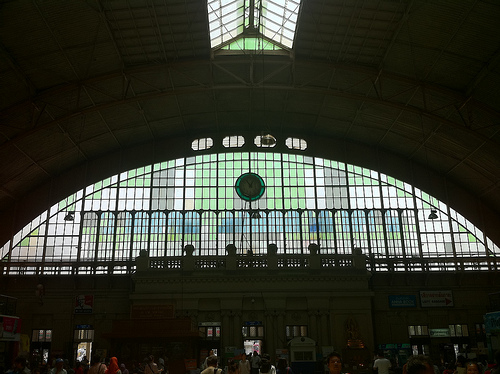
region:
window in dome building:
[19, 315, 59, 347]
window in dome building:
[64, 319, 103, 343]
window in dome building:
[233, 315, 271, 341]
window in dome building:
[272, 318, 314, 339]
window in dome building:
[400, 316, 430, 340]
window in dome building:
[441, 312, 470, 349]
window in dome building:
[176, 131, 223, 157]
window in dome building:
[213, 126, 249, 157]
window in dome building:
[246, 124, 278, 153]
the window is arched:
[17, 150, 432, 225]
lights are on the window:
[115, 219, 492, 362]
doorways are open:
[21, 320, 123, 367]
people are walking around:
[182, 338, 256, 373]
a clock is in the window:
[208, 165, 372, 215]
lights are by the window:
[52, 192, 146, 268]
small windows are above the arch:
[176, 125, 458, 215]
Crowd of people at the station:
[6, 342, 484, 370]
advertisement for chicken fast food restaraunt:
[75, 292, 92, 309]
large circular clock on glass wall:
[235, 170, 265, 202]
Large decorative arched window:
[2, 153, 499, 258]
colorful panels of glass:
[169, 211, 203, 238]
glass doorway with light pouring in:
[239, 331, 266, 363]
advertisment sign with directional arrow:
[417, 289, 456, 309]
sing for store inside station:
[0, 317, 20, 342]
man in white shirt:
[371, 352, 393, 372]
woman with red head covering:
[105, 355, 122, 372]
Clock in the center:
[236, 171, 264, 201]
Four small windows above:
[186, 130, 315, 153]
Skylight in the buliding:
[206, 0, 301, 55]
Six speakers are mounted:
[136, 238, 367, 263]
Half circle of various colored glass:
[0, 150, 499, 277]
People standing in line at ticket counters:
[0, 345, 495, 370]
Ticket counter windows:
[30, 320, 480, 345]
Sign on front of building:
[415, 282, 455, 308]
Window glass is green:
[220, 31, 282, 51]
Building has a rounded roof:
[1, 0, 498, 242]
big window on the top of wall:
[2, 147, 499, 274]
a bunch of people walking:
[23, 342, 488, 372]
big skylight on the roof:
[207, 0, 300, 56]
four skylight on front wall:
[189, 131, 309, 150]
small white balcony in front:
[131, 243, 376, 318]